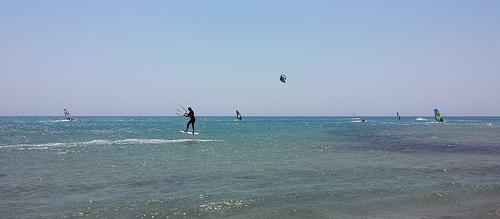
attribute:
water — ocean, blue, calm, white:
[0, 117, 499, 218]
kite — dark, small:
[279, 74, 286, 83]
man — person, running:
[182, 106, 196, 135]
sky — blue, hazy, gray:
[0, 1, 499, 117]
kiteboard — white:
[181, 130, 200, 135]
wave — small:
[0, 137, 223, 150]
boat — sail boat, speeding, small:
[63, 109, 76, 121]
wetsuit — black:
[186, 110, 196, 131]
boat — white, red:
[235, 110, 242, 121]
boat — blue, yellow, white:
[433, 108, 444, 122]